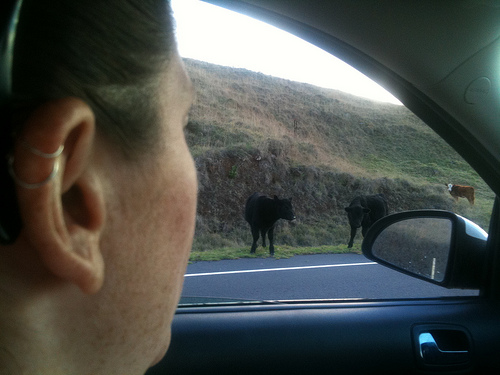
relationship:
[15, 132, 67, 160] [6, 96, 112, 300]
earring in ear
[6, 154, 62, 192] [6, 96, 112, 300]
earring in ear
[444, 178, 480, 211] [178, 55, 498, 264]
cow in grass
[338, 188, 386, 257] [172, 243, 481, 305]
cow near street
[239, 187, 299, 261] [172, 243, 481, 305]
cow near street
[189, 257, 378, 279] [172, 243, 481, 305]
line in street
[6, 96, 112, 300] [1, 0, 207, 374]
ear of girl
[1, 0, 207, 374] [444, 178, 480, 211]
girl looking cow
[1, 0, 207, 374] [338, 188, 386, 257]
girl looking cow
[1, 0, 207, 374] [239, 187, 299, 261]
girl looking cow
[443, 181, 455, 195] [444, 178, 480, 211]
head of cow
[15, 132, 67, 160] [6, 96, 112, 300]
earring on ear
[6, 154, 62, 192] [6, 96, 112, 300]
earring on ear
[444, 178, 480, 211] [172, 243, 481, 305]
cow on street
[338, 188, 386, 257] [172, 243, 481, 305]
cow on street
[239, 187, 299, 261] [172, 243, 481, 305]
cow on street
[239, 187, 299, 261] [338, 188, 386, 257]
cow looking cow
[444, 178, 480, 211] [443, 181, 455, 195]
cow with head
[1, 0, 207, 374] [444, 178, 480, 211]
girl seeing cow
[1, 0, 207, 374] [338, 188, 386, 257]
girl seeing cow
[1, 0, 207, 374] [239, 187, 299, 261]
girl seeing cow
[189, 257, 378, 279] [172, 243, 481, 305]
line on street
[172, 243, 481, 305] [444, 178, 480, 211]
street front cow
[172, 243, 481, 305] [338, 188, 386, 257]
street front cow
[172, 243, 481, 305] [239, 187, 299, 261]
street front cow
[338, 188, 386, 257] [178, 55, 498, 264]
cow in grass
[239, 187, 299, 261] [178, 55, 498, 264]
cow in grass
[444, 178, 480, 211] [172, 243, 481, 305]
cow near street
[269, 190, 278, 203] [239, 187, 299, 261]
ear of cow